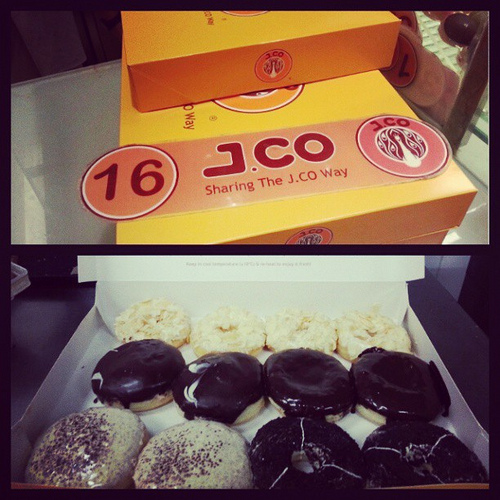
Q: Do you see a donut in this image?
A: Yes, there is a donut.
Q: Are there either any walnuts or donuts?
A: Yes, there is a donut.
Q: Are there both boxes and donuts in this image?
A: Yes, there are both a donut and a box.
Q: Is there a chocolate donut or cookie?
A: Yes, there is a chocolate donut.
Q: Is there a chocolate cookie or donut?
A: Yes, there is a chocolate donut.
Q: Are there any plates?
A: No, there are no plates.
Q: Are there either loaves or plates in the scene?
A: No, there are no plates or loaves.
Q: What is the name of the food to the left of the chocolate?
A: The food is a donut.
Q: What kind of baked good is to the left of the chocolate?
A: The food is a donut.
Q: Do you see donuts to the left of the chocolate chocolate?
A: Yes, there is a donut to the left of the chocolate.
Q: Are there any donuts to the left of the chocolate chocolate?
A: Yes, there is a donut to the left of the chocolate.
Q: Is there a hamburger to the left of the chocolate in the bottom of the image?
A: No, there is a donut to the left of the chocolate.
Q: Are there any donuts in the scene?
A: Yes, there is a donut.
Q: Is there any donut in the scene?
A: Yes, there is a donut.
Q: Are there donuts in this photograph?
A: Yes, there is a donut.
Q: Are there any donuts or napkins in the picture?
A: Yes, there is a donut.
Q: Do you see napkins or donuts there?
A: Yes, there is a donut.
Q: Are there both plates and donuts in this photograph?
A: No, there is a donut but no plates.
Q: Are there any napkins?
A: No, there are no napkins.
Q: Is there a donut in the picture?
A: Yes, there is a donut.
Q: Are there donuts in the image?
A: Yes, there is a donut.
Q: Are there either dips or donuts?
A: Yes, there is a donut.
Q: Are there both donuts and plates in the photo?
A: No, there is a donut but no plates.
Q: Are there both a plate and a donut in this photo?
A: No, there is a donut but no plates.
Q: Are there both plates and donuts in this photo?
A: No, there is a donut but no plates.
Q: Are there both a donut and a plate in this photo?
A: No, there is a donut but no plates.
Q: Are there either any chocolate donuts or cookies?
A: Yes, there is a chocolate donut.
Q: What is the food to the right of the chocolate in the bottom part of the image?
A: The food is a donut.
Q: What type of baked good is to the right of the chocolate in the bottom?
A: The food is a donut.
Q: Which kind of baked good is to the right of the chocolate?
A: The food is a donut.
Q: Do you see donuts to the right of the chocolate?
A: Yes, there is a donut to the right of the chocolate.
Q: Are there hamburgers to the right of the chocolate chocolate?
A: No, there is a donut to the right of the chocolate.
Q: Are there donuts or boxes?
A: Yes, there is a donut.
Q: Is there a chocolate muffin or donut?
A: Yes, there is a chocolate donut.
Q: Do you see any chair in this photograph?
A: No, there are no chairs.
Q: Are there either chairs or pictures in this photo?
A: No, there are no chairs or pictures.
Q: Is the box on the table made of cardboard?
A: Yes, the box is made of cardboard.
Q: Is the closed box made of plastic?
A: No, the box is made of cardboard.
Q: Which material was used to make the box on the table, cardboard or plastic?
A: The box is made of cardboard.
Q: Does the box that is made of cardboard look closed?
A: Yes, the box is closed.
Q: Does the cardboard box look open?
A: No, the box is closed.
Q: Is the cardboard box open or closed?
A: The box is closed.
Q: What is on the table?
A: The box is on the table.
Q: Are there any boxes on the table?
A: Yes, there is a box on the table.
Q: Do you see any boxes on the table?
A: Yes, there is a box on the table.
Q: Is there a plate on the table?
A: No, there is a box on the table.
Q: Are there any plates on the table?
A: No, there is a box on the table.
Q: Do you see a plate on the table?
A: No, there is a box on the table.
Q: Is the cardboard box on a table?
A: Yes, the box is on a table.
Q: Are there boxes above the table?
A: Yes, there is a box above the table.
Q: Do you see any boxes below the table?
A: No, the box is above the table.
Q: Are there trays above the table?
A: No, there is a box above the table.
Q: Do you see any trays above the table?
A: No, there is a box above the table.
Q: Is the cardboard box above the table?
A: Yes, the box is above the table.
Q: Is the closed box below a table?
A: No, the box is above a table.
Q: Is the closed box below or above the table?
A: The box is above the table.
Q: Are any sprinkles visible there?
A: Yes, there are sprinkles.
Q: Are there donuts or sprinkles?
A: Yes, there are sprinkles.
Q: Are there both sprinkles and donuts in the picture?
A: Yes, there are both sprinkles and a donut.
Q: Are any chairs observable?
A: No, there are no chairs.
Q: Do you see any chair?
A: No, there are no chairs.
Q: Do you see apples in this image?
A: No, there are no apples.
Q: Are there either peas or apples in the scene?
A: No, there are no apples or peas.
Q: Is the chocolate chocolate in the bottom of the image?
A: Yes, the chocolate is in the bottom of the image.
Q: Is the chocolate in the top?
A: No, the chocolate is in the bottom of the image.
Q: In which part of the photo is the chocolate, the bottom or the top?
A: The chocolate is in the bottom of the image.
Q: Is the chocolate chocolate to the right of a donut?
A: No, the chocolate is to the left of a donut.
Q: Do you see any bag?
A: No, there are no bags.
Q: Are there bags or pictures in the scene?
A: No, there are no bags or pictures.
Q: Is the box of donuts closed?
A: No, the box is open.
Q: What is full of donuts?
A: The box is full of donuts.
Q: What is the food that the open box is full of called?
A: The food is donuts.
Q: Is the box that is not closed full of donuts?
A: Yes, the box is full of donuts.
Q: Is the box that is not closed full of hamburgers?
A: No, the box is full of donuts.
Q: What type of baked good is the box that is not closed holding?
A: The box is holding the doughnuts.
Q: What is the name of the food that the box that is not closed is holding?
A: The food is donuts.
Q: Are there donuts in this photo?
A: Yes, there are donuts.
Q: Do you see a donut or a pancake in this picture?
A: Yes, there are donuts.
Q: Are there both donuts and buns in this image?
A: No, there are donuts but no buns.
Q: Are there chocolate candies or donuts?
A: Yes, there are chocolate donuts.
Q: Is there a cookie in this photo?
A: No, there are no cookies.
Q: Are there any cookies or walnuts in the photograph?
A: No, there are no cookies or walnuts.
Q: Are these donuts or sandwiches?
A: These are donuts.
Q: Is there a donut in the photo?
A: Yes, there are donuts.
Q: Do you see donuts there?
A: Yes, there are donuts.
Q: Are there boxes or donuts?
A: Yes, there are donuts.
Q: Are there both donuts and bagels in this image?
A: No, there are donuts but no bagels.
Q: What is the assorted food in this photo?
A: The food is donuts.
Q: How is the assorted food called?
A: The food is donuts.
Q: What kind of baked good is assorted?
A: The baked good is donuts.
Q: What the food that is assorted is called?
A: The food is donuts.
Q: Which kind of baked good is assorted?
A: The baked good is donuts.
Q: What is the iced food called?
A: The food is donuts.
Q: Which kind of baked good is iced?
A: The baked good is donuts.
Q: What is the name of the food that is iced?
A: The food is donuts.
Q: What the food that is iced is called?
A: The food is donuts.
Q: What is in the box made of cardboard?
A: The doughnuts are in the box.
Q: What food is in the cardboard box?
A: The food is donuts.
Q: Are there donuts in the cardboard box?
A: Yes, there are donuts in the box.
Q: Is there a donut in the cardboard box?
A: Yes, there are donuts in the box.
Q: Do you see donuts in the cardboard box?
A: Yes, there are donuts in the box.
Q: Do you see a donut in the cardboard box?
A: Yes, there are donuts in the box.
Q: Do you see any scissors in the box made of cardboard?
A: No, there are donuts in the box.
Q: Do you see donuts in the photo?
A: Yes, there are donuts.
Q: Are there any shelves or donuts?
A: Yes, there are donuts.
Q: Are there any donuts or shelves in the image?
A: Yes, there are donuts.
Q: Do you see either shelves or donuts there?
A: Yes, there are donuts.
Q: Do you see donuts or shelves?
A: Yes, there are donuts.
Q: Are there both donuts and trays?
A: No, there are donuts but no trays.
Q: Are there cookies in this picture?
A: No, there are no cookies.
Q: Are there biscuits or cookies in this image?
A: No, there are no cookies or biscuits.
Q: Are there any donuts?
A: Yes, there are donuts.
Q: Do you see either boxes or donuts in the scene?
A: Yes, there are donuts.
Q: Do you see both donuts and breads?
A: No, there are donuts but no breads.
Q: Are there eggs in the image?
A: No, there are no eggs.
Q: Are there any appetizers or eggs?
A: No, there are no eggs or appetizers.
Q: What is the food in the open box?
A: The food is donuts.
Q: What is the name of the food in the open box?
A: The food is donuts.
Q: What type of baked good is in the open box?
A: The food is donuts.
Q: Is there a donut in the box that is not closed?
A: Yes, there are donuts in the box.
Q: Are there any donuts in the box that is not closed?
A: Yes, there are donuts in the box.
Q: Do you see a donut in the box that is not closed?
A: Yes, there are donuts in the box.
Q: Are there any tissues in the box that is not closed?
A: No, there are donuts in the box.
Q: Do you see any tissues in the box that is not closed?
A: No, there are donuts in the box.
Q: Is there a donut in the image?
A: Yes, there are donuts.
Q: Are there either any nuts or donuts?
A: Yes, there are donuts.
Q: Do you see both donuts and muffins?
A: No, there are donuts but no muffins.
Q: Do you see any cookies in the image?
A: No, there are no cookies.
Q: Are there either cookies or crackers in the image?
A: No, there are no cookies or crackers.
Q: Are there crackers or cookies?
A: No, there are no cookies or crackers.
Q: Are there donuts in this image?
A: Yes, there is a donut.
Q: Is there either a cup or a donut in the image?
A: Yes, there is a donut.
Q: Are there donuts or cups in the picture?
A: Yes, there is a donut.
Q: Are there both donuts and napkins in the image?
A: No, there is a donut but no napkins.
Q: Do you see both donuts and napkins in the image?
A: No, there is a donut but no napkins.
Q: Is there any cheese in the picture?
A: No, there is no cheese.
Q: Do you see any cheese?
A: No, there is no cheese.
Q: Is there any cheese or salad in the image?
A: No, there are no cheese or salad.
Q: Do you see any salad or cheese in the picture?
A: No, there are no cheese or salad.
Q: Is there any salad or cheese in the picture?
A: No, there are no cheese or salad.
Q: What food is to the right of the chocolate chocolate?
A: The food is a donut.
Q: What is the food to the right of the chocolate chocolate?
A: The food is a donut.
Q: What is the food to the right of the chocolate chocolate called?
A: The food is a donut.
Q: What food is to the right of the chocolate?
A: The food is a donut.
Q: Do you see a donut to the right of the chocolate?
A: Yes, there is a donut to the right of the chocolate.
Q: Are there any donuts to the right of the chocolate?
A: Yes, there is a donut to the right of the chocolate.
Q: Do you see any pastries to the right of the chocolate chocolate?
A: No, there is a donut to the right of the chocolate.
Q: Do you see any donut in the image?
A: Yes, there is a donut.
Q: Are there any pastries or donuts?
A: Yes, there is a donut.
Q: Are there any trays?
A: No, there are no trays.